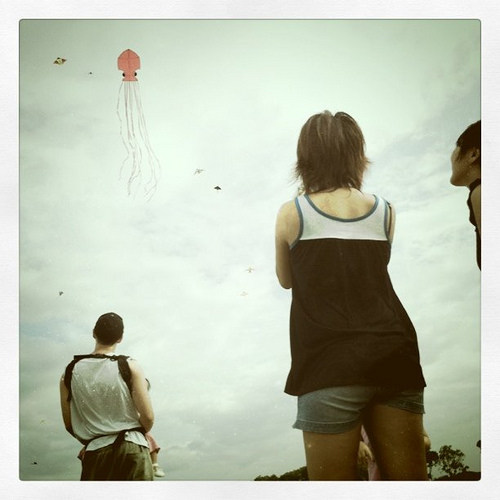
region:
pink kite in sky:
[116, 50, 141, 83]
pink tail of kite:
[116, 79, 158, 191]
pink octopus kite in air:
[118, 51, 158, 198]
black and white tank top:
[286, 197, 423, 387]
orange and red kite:
[53, 55, 65, 63]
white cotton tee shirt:
[63, 356, 151, 449]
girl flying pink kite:
[277, 111, 434, 481]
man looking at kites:
[58, 311, 164, 483]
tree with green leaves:
[432, 441, 467, 479]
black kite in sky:
[213, 184, 221, 190]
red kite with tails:
[103, 33, 171, 206]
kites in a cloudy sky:
[47, 37, 174, 204]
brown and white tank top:
[253, 181, 440, 401]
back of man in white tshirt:
[53, 307, 163, 462]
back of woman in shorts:
[270, 106, 439, 474]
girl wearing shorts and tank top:
[267, 100, 432, 481]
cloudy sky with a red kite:
[110, 41, 177, 210]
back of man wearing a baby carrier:
[60, 307, 170, 480]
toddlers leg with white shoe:
[140, 432, 170, 477]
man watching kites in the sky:
[48, 38, 160, 470]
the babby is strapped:
[76, 331, 209, 494]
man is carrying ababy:
[62, 310, 182, 495]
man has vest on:
[69, 348, 173, 459]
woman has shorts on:
[265, 120, 440, 498]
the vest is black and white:
[283, 198, 413, 373]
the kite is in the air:
[113, 36, 181, 179]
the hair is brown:
[297, 107, 384, 182]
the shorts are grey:
[298, 393, 426, 445]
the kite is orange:
[113, 47, 141, 92]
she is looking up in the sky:
[440, 127, 487, 238]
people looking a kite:
[48, 39, 488, 481]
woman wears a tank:
[270, 105, 430, 483]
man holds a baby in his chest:
[56, 308, 166, 481]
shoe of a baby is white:
[151, 458, 171, 480]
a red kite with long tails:
[101, 41, 166, 201]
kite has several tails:
[108, 43, 164, 210]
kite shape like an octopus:
[106, 47, 170, 201]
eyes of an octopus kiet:
[116, 67, 138, 84]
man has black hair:
[67, 303, 144, 369]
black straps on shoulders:
[61, 349, 138, 396]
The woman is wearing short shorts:
[293, 379, 420, 424]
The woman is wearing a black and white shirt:
[278, 198, 410, 362]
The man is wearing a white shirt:
[65, 355, 142, 432]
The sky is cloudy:
[149, 257, 258, 409]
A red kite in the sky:
[114, 48, 152, 99]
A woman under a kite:
[264, 109, 423, 469]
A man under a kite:
[53, 310, 163, 477]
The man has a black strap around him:
[109, 353, 131, 375]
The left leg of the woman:
[295, 400, 359, 479]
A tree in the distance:
[438, 440, 470, 471]